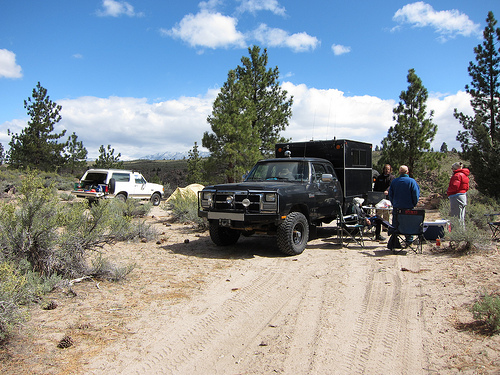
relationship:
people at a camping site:
[352, 155, 479, 251] [4, 170, 447, 284]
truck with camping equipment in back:
[69, 163, 169, 210] [62, 168, 109, 215]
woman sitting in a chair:
[329, 188, 369, 289] [397, 268, 438, 333]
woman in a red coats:
[437, 150, 477, 239] [443, 169, 474, 197]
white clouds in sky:
[3, 89, 495, 157] [93, 49, 207, 112]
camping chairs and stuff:
[331, 202, 498, 256] [73, 183, 108, 193]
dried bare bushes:
[29, 118, 173, 321] [14, 193, 128, 279]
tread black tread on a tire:
[275, 225, 290, 230] [280, 215, 310, 257]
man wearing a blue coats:
[385, 162, 420, 261] [385, 173, 419, 208]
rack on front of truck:
[197, 187, 284, 221] [194, 127, 388, 257]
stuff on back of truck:
[73, 183, 108, 193] [69, 168, 165, 210]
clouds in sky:
[109, 57, 201, 137] [0, 49, 480, 89]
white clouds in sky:
[0, 82, 495, 161] [1, 4, 498, 154]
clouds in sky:
[161, 0, 353, 60] [1, 4, 498, 154]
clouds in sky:
[1, 1, 499, 148] [1, 4, 498, 154]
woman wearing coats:
[437, 160, 470, 237] [448, 169, 475, 190]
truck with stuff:
[194, 127, 388, 257] [65, 156, 166, 214]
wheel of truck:
[274, 209, 311, 256] [194, 136, 374, 256]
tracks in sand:
[134, 246, 414, 373] [124, 237, 470, 366]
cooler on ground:
[421, 218, 448, 235] [421, 245, 452, 262]